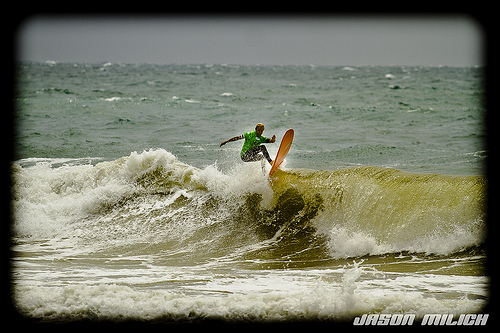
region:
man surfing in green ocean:
[220, 105, 304, 185]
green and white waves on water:
[33, 213, 122, 289]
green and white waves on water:
[46, 148, 96, 197]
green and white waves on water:
[46, 75, 110, 138]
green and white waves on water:
[168, 221, 331, 301]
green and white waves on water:
[349, 206, 447, 270]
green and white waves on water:
[337, 150, 428, 207]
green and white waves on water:
[140, 125, 196, 200]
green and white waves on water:
[378, 75, 458, 145]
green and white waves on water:
[132, 66, 219, 118]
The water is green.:
[57, 76, 227, 149]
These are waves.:
[40, 163, 380, 281]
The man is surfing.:
[175, 105, 339, 214]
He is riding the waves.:
[166, 88, 426, 248]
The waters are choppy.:
[49, 49, 464, 294]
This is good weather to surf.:
[51, 52, 467, 294]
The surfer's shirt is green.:
[233, 122, 272, 162]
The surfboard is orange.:
[276, 123, 306, 201]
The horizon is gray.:
[58, 28, 470, 64]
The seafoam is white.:
[66, 282, 469, 317]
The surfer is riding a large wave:
[204, 97, 316, 181]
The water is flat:
[69, 73, 244, 150]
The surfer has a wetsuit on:
[222, 107, 282, 181]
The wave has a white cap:
[35, 148, 142, 228]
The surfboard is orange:
[263, 126, 313, 194]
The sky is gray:
[218, 25, 340, 60]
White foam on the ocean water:
[179, 263, 342, 320]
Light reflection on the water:
[171, 207, 318, 312]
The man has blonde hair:
[245, 110, 267, 141]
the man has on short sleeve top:
[230, 123, 274, 178]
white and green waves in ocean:
[26, 142, 97, 210]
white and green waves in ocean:
[26, 212, 103, 257]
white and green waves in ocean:
[32, 248, 220, 296]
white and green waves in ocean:
[210, 241, 342, 279]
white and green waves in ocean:
[120, 138, 181, 218]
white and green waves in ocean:
[359, 156, 431, 251]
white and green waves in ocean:
[52, 65, 142, 97]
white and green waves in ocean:
[350, 68, 462, 139]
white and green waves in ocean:
[136, 71, 211, 123]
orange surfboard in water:
[269, 127, 296, 172]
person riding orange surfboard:
[217, 122, 295, 176]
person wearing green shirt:
[240, 132, 270, 158]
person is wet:
[217, 122, 274, 175]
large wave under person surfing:
[13, 146, 489, 264]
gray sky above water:
[16, 16, 482, 67]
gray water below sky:
[21, 63, 486, 318]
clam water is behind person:
[10, 63, 485, 171]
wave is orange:
[125, 148, 490, 280]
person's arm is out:
[217, 132, 243, 150]